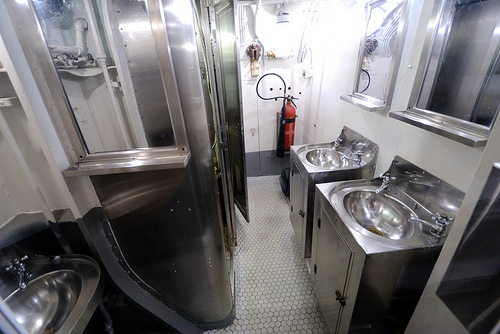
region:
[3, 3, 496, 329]
a compact bathroom in a limited space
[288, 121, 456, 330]
two sinks side by side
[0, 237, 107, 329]
another sink off to the left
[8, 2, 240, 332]
the shower is tiny and cramped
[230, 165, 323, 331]
the floor is narrow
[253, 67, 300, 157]
fire extinguisher against the far wall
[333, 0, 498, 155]
mirrors mounted over the sinks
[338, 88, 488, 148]
little shelves in front of the mirrors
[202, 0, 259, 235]
the shower door is very narrow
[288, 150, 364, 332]
small cabinets under the sinks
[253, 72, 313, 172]
red fire extinguisher on floor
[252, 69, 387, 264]
red fire extinguisher next to sink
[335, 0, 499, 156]
stainless steel mirrors on wall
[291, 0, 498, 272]
mirrors above stainless steel sinks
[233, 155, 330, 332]
white tessellation patterned tile floor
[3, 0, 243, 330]
stainless steel mirror to the side of a sink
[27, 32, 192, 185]
white pipe reflected in steel mirror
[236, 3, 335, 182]
red extinguisher under conduit and valves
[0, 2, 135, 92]
drain pipes and conduits in mirror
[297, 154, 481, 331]
Stainless steel sink and cabinet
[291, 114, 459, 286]
two stainless steel public bathroom sinks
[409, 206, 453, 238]
one shiny metal bathroom faucet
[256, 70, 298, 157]
one red long fire extinguisher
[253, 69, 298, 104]
thin black fire extinguisher hose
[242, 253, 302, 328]
white honeycomb bathroom floor tile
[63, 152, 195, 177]
one stainless steel windowsill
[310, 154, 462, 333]
stainless steel bathroom vanity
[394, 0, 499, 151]
mirror with stainless steel ledge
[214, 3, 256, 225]
one open rectangular stainless steel door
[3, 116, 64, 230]
one thin metal white painted pipe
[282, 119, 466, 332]
two silver sinks on the wall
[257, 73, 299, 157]
fire extinguisher on the wall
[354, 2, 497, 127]
mirrors above the sinks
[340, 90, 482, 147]
shelves on the mirrors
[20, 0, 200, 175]
mirror on the left side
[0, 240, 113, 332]
sink on the left side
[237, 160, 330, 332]
white flooring in the bathroom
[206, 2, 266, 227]
glass door to the shower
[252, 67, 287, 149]
black hose on the fire extinguisher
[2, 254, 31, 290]
faucet on the sink on the left side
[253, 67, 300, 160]
a fire extinguisher is hanging on the wall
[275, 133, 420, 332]
two free standing sinks are in the room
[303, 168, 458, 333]
the sink is made of stainless steel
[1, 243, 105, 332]
a third sink is in the corner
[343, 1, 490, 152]
two windows are above the sinks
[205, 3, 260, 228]
a door is slightly open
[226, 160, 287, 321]
a cupboard is under the sink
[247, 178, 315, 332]
the floor has a honey comb pattern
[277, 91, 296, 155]
the extinguisher is red in color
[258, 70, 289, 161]
the CO2 hose for the extinguisher